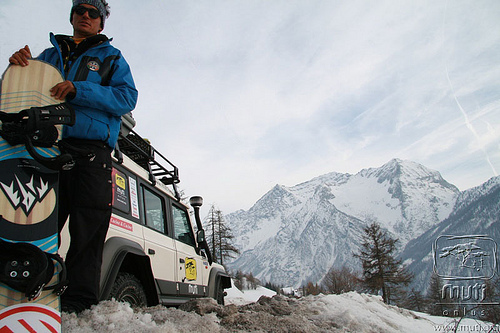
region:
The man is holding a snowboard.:
[1, 0, 140, 331]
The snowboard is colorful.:
[1, 49, 73, 331]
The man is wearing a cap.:
[58, 0, 113, 44]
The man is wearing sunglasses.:
[61, 0, 112, 40]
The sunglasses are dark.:
[63, 0, 110, 39]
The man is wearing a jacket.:
[7, 0, 141, 162]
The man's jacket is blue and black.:
[8, 0, 140, 161]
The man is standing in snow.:
[3, 0, 232, 332]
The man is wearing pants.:
[1, 0, 166, 331]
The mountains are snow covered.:
[195, 115, 499, 330]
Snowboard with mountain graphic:
[0, 55, 66, 330]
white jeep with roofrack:
[100, 145, 230, 310]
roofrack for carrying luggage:
[111, 107, 177, 182]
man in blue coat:
[31, 1, 143, 298]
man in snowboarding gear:
[4, 0, 138, 301]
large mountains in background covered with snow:
[244, 151, 498, 301]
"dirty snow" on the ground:
[62, 291, 347, 327]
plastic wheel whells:
[100, 236, 161, 303]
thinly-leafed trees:
[196, 197, 241, 270]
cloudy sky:
[189, 6, 494, 185]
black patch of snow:
[212, 302, 312, 328]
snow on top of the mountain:
[345, 170, 393, 207]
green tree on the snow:
[346, 212, 415, 301]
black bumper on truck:
[194, 263, 258, 306]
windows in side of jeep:
[136, 186, 204, 228]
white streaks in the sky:
[435, 89, 479, 132]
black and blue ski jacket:
[57, 39, 152, 127]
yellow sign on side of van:
[161, 255, 212, 285]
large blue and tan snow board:
[2, 44, 82, 256]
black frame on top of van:
[129, 126, 207, 182]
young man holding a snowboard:
[0, 0, 235, 331]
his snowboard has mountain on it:
[2, 163, 58, 219]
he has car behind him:
[100, 110, 241, 305]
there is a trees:
[292, 223, 468, 294]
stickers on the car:
[113, 168, 140, 221]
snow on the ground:
[298, 292, 418, 332]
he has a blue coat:
[68, 46, 123, 132]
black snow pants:
[61, 140, 115, 315]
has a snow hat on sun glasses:
[64, 2, 112, 37]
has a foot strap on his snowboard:
[1, 106, 61, 152]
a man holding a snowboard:
[1, 0, 143, 312]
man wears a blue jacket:
[8, 0, 145, 312]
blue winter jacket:
[8, 28, 144, 153]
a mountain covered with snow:
[222, 150, 497, 290]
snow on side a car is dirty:
[93, 278, 382, 332]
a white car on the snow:
[111, 125, 245, 303]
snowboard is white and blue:
[3, 55, 73, 327]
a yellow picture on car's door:
[175, 247, 204, 284]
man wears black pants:
[13, 4, 143, 314]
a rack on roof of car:
[123, 126, 187, 196]